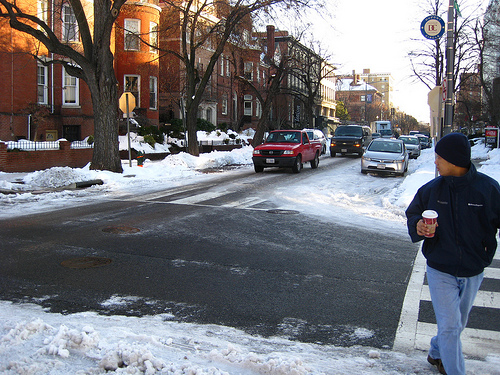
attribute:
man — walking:
[399, 117, 491, 368]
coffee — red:
[410, 206, 443, 244]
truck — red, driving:
[244, 115, 332, 178]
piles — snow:
[126, 148, 231, 186]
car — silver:
[365, 139, 411, 181]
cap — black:
[407, 128, 479, 172]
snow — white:
[0, 156, 233, 202]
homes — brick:
[1, 10, 400, 113]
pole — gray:
[435, 14, 469, 139]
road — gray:
[0, 192, 374, 338]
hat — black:
[432, 129, 487, 170]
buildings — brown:
[197, 5, 409, 138]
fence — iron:
[17, 130, 87, 152]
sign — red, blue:
[480, 121, 495, 150]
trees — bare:
[397, 5, 491, 92]